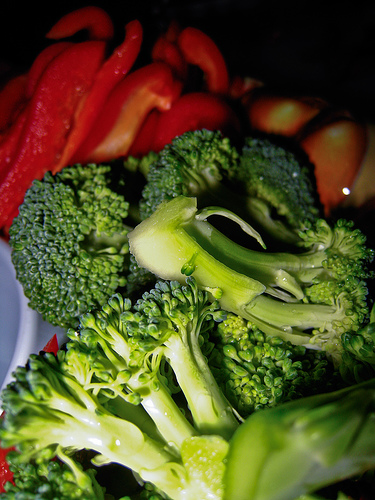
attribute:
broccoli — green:
[127, 193, 373, 377]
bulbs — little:
[21, 227, 80, 283]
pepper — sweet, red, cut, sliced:
[0, 6, 238, 243]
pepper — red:
[6, 48, 92, 227]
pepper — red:
[79, 25, 135, 166]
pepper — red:
[103, 64, 161, 171]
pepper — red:
[176, 23, 235, 97]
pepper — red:
[148, 32, 182, 92]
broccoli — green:
[9, 140, 352, 488]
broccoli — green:
[117, 188, 373, 368]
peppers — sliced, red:
[1, 3, 232, 240]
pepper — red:
[1, 40, 106, 241]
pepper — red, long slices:
[52, 18, 141, 173]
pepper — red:
[0, 101, 27, 180]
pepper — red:
[24, 40, 72, 99]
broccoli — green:
[11, 168, 366, 495]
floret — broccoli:
[219, 341, 259, 379]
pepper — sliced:
[7, 6, 196, 164]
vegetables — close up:
[7, 40, 374, 471]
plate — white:
[0, 236, 71, 391]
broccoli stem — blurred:
[205, 380, 373, 497]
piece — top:
[11, 158, 155, 329]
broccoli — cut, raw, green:
[0, 127, 373, 498]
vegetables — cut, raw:
[34, 129, 359, 466]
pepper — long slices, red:
[0, 42, 104, 228]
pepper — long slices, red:
[67, 62, 181, 163]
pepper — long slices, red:
[151, 91, 227, 152]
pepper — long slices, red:
[180, 27, 227, 91]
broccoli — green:
[0, 157, 137, 345]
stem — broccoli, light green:
[171, 349, 222, 402]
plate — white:
[0, 232, 72, 420]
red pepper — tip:
[41, 333, 60, 358]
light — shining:
[39, 331, 217, 500]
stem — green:
[161, 331, 241, 444]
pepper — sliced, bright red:
[3, 7, 374, 243]